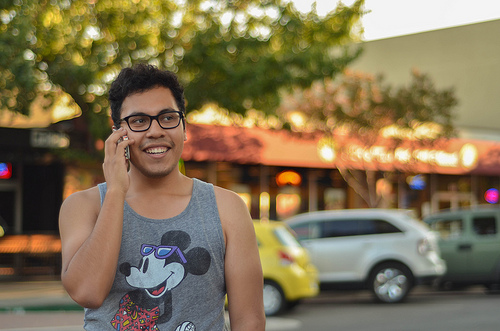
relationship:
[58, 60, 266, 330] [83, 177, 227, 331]
man wearing tank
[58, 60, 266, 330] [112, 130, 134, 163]
man on cell phone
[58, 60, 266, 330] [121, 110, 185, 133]
man wearing glasses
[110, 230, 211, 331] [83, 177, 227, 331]
mickey mouse on tank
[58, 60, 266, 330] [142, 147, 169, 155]
man has teeth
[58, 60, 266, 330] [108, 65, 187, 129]
man has hair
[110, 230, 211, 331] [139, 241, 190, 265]
mickey mouse has sunglasses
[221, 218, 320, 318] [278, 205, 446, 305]
car next to car